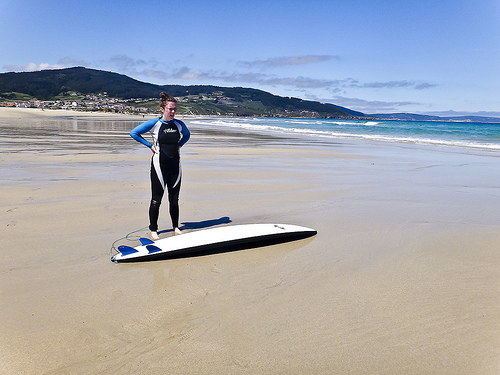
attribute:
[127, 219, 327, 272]
board — white, upside-down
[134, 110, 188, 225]
wetsuit — black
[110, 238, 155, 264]
fins — blue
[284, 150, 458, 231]
beach — sandy, large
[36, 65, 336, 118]
mountains — forested, green, in distance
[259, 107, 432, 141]
waves — breaking, white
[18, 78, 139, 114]
village — small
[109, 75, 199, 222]
woman — barefoot, standing, angry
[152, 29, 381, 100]
clouds — ominous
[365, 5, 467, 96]
sky — clear, blue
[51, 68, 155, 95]
hillside — green, rolling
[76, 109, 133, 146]
water — standing, reflective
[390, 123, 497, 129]
water — blue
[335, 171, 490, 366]
sand — smooth